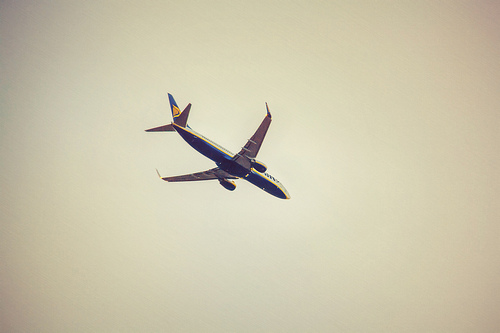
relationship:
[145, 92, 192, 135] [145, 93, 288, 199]
tail of airplane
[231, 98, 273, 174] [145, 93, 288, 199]
right wing on airplane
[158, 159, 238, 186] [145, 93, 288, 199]
wing on airplane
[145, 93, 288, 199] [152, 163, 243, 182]
airplane has wing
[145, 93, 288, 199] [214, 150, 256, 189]
airplane has engine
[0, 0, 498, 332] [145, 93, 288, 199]
sky surrounding airplane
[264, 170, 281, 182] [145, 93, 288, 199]
windows on side of airplane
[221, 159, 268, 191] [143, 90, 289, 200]
engines are on plane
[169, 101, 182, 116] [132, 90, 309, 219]
lettering on plane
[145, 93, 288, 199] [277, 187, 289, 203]
airplane has nose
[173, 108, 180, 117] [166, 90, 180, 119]
yellow logo on blue tail